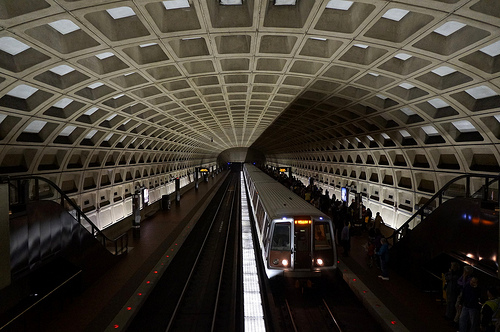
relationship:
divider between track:
[237, 166, 262, 330] [116, 162, 242, 327]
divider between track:
[237, 166, 262, 330] [261, 285, 392, 325]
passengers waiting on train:
[255, 155, 443, 303] [232, 157, 349, 294]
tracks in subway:
[278, 284, 300, 330] [5, 1, 499, 328]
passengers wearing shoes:
[255, 155, 443, 303] [378, 270, 389, 282]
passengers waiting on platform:
[255, 155, 443, 303] [305, 182, 453, 330]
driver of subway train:
[312, 223, 329, 242] [238, 155, 339, 278]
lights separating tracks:
[235, 168, 267, 329] [163, 167, 240, 328]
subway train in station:
[250, 197, 382, 302] [5, 20, 484, 320]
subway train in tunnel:
[250, 197, 382, 302] [5, 1, 495, 329]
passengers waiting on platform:
[255, 155, 443, 303] [280, 161, 479, 326]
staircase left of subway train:
[3, 173, 129, 330] [250, 197, 382, 302]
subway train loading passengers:
[250, 197, 382, 302] [255, 155, 443, 303]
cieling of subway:
[224, 4, 470, 101] [153, 103, 400, 230]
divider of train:
[237, 166, 262, 330] [237, 157, 359, 274]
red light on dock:
[134, 290, 145, 298] [66, 180, 178, 297]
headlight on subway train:
[316, 256, 324, 265] [250, 197, 382, 302]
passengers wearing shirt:
[255, 155, 443, 303] [358, 232, 431, 265]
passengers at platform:
[255, 155, 443, 303] [280, 161, 479, 326]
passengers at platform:
[255, 155, 443, 303] [3, 165, 228, 330]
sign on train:
[292, 215, 312, 225] [239, 157, 333, 286]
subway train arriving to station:
[250, 197, 382, 302] [5, 20, 484, 320]